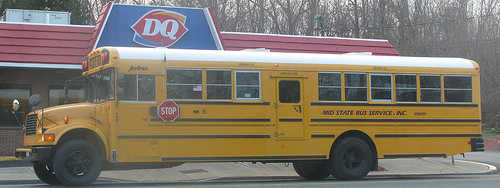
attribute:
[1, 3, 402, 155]
building — red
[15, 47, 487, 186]
bus — yellow, white on top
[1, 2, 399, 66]
roof — red